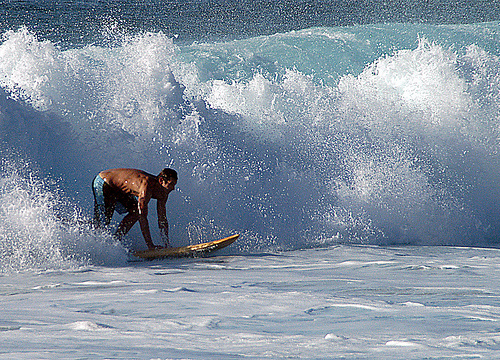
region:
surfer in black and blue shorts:
[69, 147, 191, 263]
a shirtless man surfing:
[83, 153, 195, 260]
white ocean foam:
[236, 257, 341, 332]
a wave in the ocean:
[211, 29, 426, 252]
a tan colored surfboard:
[128, 220, 244, 275]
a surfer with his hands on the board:
[109, 222, 249, 265]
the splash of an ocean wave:
[62, 7, 178, 64]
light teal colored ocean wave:
[203, 22, 400, 99]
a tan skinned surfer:
[77, 143, 209, 245]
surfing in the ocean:
[82, 160, 240, 260]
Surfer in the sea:
[81, 160, 244, 264]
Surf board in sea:
[61, 231, 246, 264]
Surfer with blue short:
[81, 160, 176, 246]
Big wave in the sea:
[1, 15, 498, 262]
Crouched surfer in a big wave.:
[78, 163, 243, 258]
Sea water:
[2, 4, 498, 356]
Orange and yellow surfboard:
[107, 232, 252, 262]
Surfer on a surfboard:
[80, 162, 250, 274]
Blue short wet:
[87, 172, 139, 227]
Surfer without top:
[86, 157, 181, 255]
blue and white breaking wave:
[216, 13, 499, 220]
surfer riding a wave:
[85, 151, 242, 263]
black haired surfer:
[154, 161, 181, 198]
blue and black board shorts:
[81, 163, 141, 233]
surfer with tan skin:
[96, 161, 178, 246]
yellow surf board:
[118, 236, 265, 263]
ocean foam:
[46, 275, 453, 338]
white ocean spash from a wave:
[8, 8, 337, 163]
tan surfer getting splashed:
[42, 168, 132, 277]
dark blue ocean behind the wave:
[29, 0, 320, 16]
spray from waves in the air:
[293, 115, 378, 175]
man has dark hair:
[155, 160, 176, 177]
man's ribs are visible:
[114, 180, 135, 194]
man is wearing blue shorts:
[91, 180, 131, 220]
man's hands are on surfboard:
[122, 234, 173, 257]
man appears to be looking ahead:
[162, 179, 184, 194]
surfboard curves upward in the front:
[195, 228, 244, 256]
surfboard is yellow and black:
[129, 230, 246, 262]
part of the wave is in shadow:
[18, 111, 80, 181]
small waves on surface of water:
[54, 276, 380, 331]